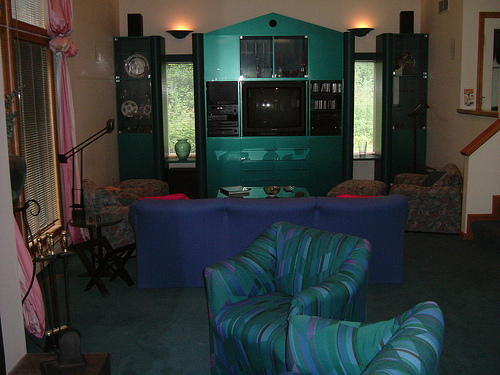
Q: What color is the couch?
A: Blue.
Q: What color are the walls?
A: White.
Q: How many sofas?
A: One.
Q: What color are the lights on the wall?
A: Yellow.